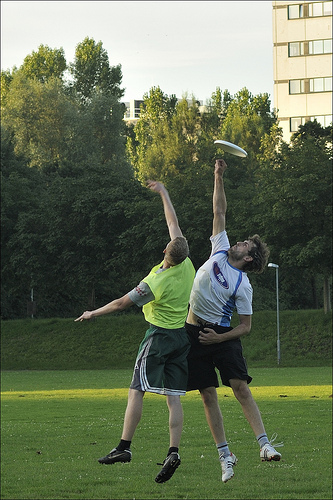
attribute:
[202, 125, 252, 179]
frisbee — white, flying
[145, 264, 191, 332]
vest — green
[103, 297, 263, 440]
shorts — green, black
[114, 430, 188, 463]
socks — black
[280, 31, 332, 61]
windows — visble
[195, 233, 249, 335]
teeshirt — gray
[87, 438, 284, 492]
shoes — black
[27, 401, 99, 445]
ground — green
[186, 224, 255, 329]
shirt — raised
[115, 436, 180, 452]
socks — black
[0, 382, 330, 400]
light — blight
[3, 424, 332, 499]
grass — green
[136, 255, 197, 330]
shirt — bright colored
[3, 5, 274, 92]
sky — clear